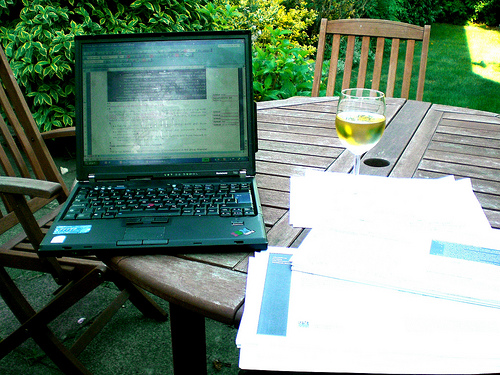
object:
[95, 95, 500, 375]
table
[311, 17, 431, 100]
chair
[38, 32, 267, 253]
laptop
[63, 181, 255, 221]
keyboard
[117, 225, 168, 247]
touchpad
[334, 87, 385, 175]
glass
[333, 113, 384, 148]
wine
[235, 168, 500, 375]
paper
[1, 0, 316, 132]
bush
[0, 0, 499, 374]
backyard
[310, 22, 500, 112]
grass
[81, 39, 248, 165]
screen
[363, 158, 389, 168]
hole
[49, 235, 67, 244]
sticker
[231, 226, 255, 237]
logo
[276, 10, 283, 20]
flower